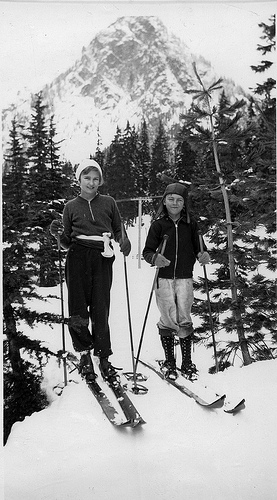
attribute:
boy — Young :
[51, 147, 132, 377]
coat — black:
[152, 221, 195, 276]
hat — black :
[153, 171, 209, 215]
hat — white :
[65, 157, 113, 179]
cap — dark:
[150, 180, 192, 220]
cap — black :
[152, 180, 195, 223]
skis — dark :
[28, 171, 254, 424]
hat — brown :
[157, 178, 191, 198]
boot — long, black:
[157, 328, 177, 381]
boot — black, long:
[178, 333, 199, 379]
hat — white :
[65, 144, 106, 187]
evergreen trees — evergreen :
[6, 95, 276, 254]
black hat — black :
[153, 178, 196, 225]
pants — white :
[61, 243, 123, 363]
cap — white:
[71, 152, 108, 184]